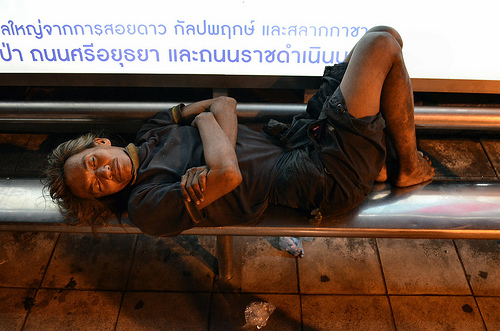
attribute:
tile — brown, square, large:
[374, 231, 478, 300]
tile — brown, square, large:
[293, 233, 391, 299]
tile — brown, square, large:
[296, 288, 399, 330]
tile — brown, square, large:
[384, 289, 489, 330]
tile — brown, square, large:
[36, 228, 142, 292]